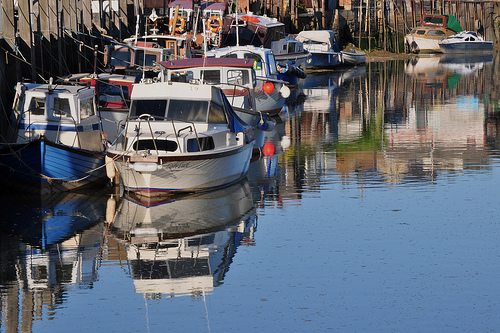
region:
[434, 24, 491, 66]
Blue and white boat in the water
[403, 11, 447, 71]
Blue and white boat in the water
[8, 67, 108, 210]
Blue and white boat in the water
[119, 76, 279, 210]
boat in the water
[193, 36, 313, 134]
boat in the water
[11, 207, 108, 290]
Reflection in the water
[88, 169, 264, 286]
Reflection in the water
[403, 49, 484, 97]
Reflection in the water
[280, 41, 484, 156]
Reflection in the water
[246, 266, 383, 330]
Ripples in the water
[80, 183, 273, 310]
reflection of a boat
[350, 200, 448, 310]
the water is murky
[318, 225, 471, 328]
the water is murky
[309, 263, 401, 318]
the water is murky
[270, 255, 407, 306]
the water is murky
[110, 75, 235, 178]
this is a motorboat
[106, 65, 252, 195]
the boat is parked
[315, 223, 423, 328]
this is the water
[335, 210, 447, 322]
the water is calm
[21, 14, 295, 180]
the harbor is full of boats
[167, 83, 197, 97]
the boat is white in color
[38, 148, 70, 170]
the boat is blue in color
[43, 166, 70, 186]
this is a rope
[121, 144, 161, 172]
the front is streamlined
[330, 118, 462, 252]
the water is clear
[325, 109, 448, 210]
calm black water of the lake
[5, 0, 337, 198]
several boats docks on the lake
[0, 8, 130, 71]
black wood posts of the dock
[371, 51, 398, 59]
brown mud on the sge of the lake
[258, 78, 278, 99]
red buoy hanging from a boat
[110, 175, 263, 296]
reflection of a boat in the water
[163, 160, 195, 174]
black lettering on the front of the boat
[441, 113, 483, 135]
tan brick wall of the building in the reflection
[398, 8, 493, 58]
two boats docked in the distance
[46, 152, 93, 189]
blue wood hull of a boat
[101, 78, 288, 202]
White boat in the water.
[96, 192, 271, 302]
A reflection of the boat in the water.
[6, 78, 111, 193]
A boat with a blue bottom in the water.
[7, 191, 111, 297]
Reflection of the blue bottom boat.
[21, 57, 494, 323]
A large body of water.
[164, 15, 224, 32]
Life preservers on a boat.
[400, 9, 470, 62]
A boat with a green tarp.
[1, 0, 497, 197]
Numerous boats lined up in the water.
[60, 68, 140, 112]
A boat with red trim.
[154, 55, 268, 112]
A boat with a red roof.